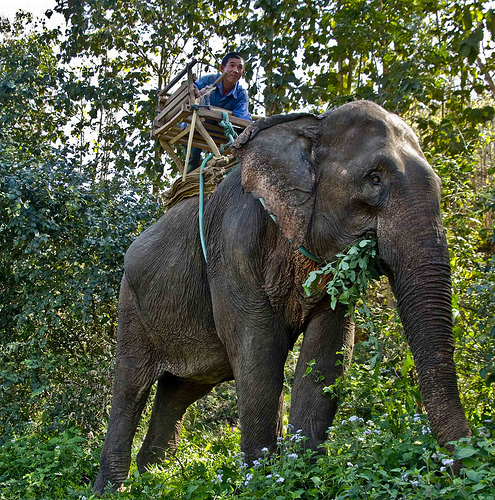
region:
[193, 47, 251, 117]
man is blue shirt crouched over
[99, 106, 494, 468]
an elephant walking in the forest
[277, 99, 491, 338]
elephant eating leaves from a tree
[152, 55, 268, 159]
a wooden chair holding a man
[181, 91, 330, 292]
green rope on elephant holding basket on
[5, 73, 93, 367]
thick trees beautiful green color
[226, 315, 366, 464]
front legs of an elephant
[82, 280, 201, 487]
back legs of the elephant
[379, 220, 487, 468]
trunk of an elephant looking in trees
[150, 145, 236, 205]
padding or blankets underneath basket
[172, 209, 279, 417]
this is an elephant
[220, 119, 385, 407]
this is an ear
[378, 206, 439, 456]
this is a trunk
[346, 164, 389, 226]
this is an eye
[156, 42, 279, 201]
this is a man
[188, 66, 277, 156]
this is a blue shirt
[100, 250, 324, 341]
the color is black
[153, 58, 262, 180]
a wooden bench on the elephant's back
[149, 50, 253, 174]
a man lying across a wooden bench on the elephant's back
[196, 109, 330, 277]
a green rope tied around the elephant's neck and body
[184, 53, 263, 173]
a man in a blue shirt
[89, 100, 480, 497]
an elephant eating green plants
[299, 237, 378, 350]
green plants in the elephant's mouth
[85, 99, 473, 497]
an elephant riding a man on the back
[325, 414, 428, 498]
green and white plants on the ground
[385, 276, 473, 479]
a truck on an elephant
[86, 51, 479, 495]
an elephant eating with a man on the back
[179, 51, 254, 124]
Man in bamboo seat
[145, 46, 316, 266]
Man riding atop elephant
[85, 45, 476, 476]
An elephant with a man on it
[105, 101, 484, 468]
A large grey elephant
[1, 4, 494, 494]
An elephant and man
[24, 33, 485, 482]
Elephant and man in woods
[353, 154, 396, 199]
An elephants right eye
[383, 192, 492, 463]
An elephants long trunk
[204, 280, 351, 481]
An elephants front legs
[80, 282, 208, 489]
An elephants back legs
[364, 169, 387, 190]
Eye of gray elephant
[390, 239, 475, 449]
Trunk of gray elephant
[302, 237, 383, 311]
foilage meal for elephant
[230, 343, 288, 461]
Leg of gray elephant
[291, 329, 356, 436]
Leg of gray elephant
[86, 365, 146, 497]
Leg of gray elephant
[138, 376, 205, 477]
Leg of gray elephant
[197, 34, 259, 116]
Man riding gray elephant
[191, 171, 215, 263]
Rope attaching basket seat to elephant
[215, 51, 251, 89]
Head of man riding elephant